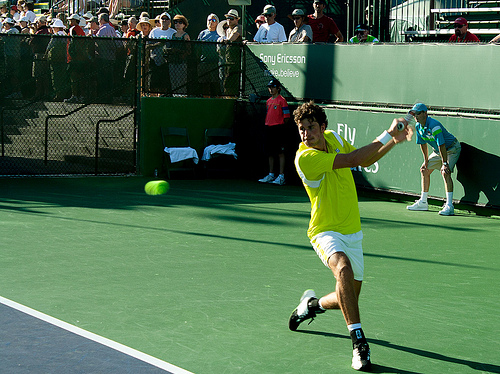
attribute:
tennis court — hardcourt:
[3, 174, 495, 372]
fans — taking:
[282, 9, 312, 46]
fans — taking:
[250, 2, 288, 47]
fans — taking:
[218, 7, 244, 94]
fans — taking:
[194, 8, 221, 90]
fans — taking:
[163, 10, 191, 95]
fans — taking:
[145, 4, 178, 91]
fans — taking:
[129, 15, 156, 93]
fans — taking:
[301, 1, 345, 43]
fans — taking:
[346, 18, 379, 48]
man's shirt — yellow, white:
[296, 140, 366, 232]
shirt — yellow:
[293, 129, 360, 233]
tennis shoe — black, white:
[285, 285, 329, 330]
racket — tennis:
[396, 109, 415, 131]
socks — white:
[299, 295, 324, 317]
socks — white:
[344, 325, 366, 342]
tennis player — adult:
[255, 102, 468, 367]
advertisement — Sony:
[256, 52, 307, 77]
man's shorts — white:
[309, 223, 365, 283]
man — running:
[289, 100, 416, 372]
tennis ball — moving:
[136, 176, 173, 198]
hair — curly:
[294, 100, 330, 129]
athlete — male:
[269, 96, 424, 371]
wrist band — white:
[377, 121, 408, 159]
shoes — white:
[271, 293, 422, 370]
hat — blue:
[407, 102, 428, 114]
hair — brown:
[288, 97, 329, 131]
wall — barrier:
[130, 95, 498, 215]